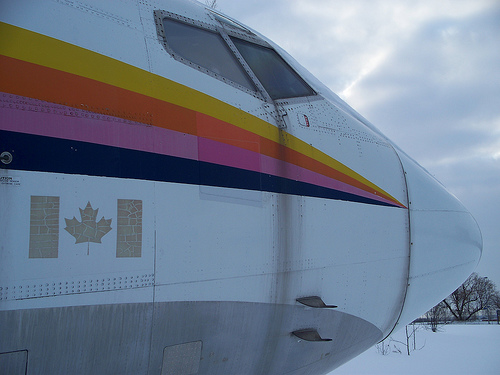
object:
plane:
[2, 1, 487, 375]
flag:
[22, 190, 145, 265]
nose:
[400, 150, 486, 333]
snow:
[318, 310, 499, 374]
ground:
[325, 317, 499, 374]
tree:
[429, 273, 500, 326]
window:
[223, 30, 322, 118]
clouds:
[273, 2, 472, 109]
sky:
[199, 2, 499, 312]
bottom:
[2, 297, 390, 375]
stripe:
[0, 21, 412, 209]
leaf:
[62, 199, 115, 261]